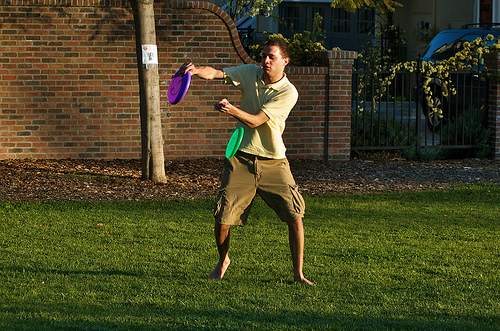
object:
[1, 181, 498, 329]
grass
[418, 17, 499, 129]
suv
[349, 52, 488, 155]
gate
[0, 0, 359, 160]
brick wall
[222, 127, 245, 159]
frisbee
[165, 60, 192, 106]
frisbee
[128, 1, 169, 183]
tree trunk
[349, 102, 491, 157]
shrubs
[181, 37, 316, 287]
man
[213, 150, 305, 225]
shorts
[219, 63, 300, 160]
shirt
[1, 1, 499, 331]
park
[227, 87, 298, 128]
arm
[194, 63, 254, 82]
arm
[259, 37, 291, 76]
head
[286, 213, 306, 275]
leg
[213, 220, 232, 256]
leg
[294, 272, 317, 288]
foot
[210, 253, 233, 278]
feet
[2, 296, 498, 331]
shadow